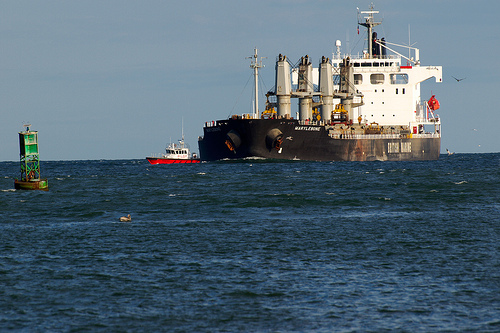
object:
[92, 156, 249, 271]
ocean waters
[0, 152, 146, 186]
water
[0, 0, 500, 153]
sky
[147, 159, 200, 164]
bottom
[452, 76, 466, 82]
bird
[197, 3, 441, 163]
bigger boat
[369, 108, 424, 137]
wall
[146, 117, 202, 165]
boat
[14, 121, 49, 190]
buoy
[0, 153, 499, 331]
ocean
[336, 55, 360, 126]
stacks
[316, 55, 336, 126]
stacks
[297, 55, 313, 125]
stacks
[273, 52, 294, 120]
stacks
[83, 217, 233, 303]
water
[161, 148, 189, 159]
top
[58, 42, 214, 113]
blue sky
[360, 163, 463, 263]
water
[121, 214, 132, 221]
bird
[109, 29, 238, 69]
clouds